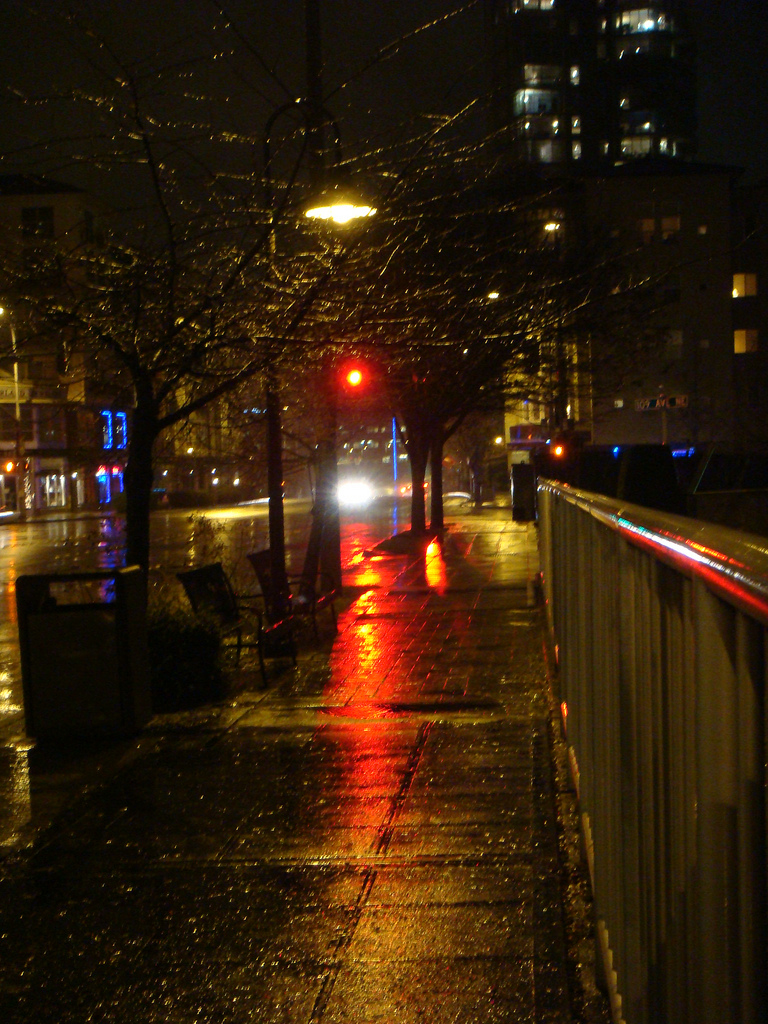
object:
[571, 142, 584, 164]
boat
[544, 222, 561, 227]
boat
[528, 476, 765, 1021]
fence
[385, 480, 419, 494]
car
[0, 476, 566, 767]
street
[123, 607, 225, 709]
bush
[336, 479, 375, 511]
headlights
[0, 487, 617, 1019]
sidewalk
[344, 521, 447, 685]
reflected light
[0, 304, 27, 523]
streetlamp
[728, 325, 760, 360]
window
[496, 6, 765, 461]
building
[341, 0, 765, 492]
building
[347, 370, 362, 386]
light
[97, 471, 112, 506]
blue sign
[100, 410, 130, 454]
window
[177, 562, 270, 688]
bench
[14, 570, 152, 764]
garbage can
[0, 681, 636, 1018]
side walk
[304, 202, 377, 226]
light